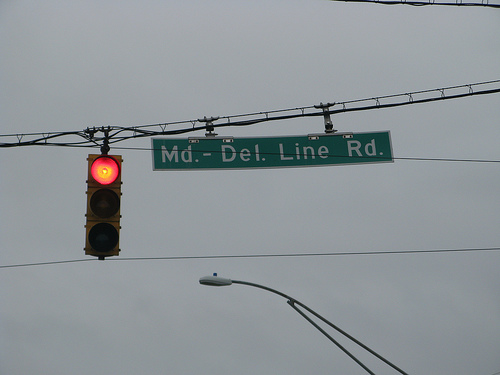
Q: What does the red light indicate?
A: Stop.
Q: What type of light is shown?
A: Traffic.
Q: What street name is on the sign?
A: Md. - Del. - Line Rd.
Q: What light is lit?
A: Red.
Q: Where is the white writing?
A: On street sign.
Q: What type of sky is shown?
A: Overcast.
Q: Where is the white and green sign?
A: Next to the traffic light.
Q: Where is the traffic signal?
A: Next to the green and white sign.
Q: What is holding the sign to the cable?
A: Metal clasps.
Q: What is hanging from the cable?
A: A traffic light and a sign?.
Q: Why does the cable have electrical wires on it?
A: To light the traffic light.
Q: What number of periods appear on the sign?
A: 3.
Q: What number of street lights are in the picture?
A: One.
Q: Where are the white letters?
A: On green sign.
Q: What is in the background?
A: Streetlight.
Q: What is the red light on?
A: Light signal.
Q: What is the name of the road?
A: Md. del. line rd.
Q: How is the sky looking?
A: Gray and cloudy.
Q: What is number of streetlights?
A: One.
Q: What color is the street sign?
A: Green.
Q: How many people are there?
A: None.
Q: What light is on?
A: Red.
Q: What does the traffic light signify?
A: To stop.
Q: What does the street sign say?
A: Md-Del.Line Rd.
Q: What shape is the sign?
A: Rectangular.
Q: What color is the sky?
A: Gray.